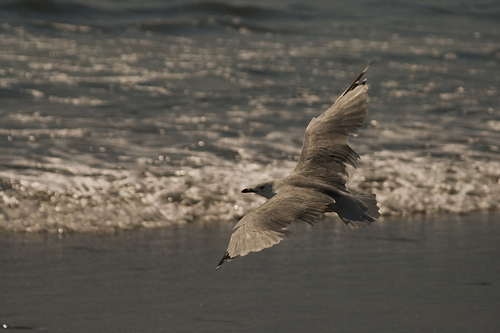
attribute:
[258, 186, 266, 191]
eye — bird's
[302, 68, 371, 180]
wing — bird's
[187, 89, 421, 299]
bird — flying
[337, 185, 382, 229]
tail — bird's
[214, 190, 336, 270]
wing — expanded, outstretched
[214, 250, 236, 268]
tip — black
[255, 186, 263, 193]
eye — small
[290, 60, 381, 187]
wing — outstretched